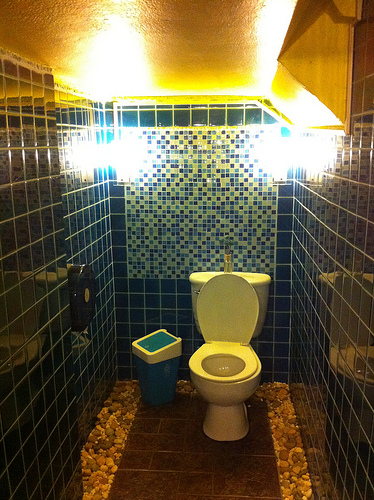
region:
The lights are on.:
[93, 123, 318, 195]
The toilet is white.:
[184, 266, 273, 447]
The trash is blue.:
[125, 326, 187, 414]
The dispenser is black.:
[58, 261, 99, 340]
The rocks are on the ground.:
[59, 376, 114, 497]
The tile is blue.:
[20, 202, 370, 413]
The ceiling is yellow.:
[4, 4, 338, 116]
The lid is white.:
[128, 327, 185, 362]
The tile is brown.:
[131, 402, 269, 498]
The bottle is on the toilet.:
[217, 234, 235, 271]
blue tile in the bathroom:
[148, 135, 290, 215]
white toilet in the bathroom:
[186, 261, 277, 430]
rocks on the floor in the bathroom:
[101, 365, 320, 497]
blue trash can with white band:
[130, 326, 206, 412]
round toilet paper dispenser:
[68, 258, 106, 358]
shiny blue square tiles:
[4, 99, 80, 440]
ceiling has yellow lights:
[45, 13, 368, 164]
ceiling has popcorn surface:
[76, 5, 234, 97]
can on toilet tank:
[213, 234, 245, 276]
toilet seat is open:
[198, 277, 256, 426]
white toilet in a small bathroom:
[188, 267, 275, 444]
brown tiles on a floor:
[107, 387, 284, 499]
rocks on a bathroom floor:
[75, 371, 316, 499]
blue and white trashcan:
[130, 321, 182, 405]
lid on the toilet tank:
[182, 265, 272, 287]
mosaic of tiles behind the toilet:
[117, 122, 277, 281]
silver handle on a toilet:
[192, 287, 212, 298]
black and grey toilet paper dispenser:
[60, 256, 100, 348]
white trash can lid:
[126, 326, 182, 367]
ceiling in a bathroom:
[0, 1, 360, 135]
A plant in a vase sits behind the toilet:
[214, 232, 238, 272]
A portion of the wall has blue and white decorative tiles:
[127, 134, 273, 236]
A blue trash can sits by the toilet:
[124, 311, 183, 414]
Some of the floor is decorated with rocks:
[266, 387, 306, 497]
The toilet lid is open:
[190, 270, 252, 383]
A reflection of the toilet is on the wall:
[0, 269, 47, 376]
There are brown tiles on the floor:
[142, 439, 183, 498]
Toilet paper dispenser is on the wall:
[63, 259, 95, 348]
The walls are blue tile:
[307, 366, 366, 478]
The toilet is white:
[184, 259, 276, 449]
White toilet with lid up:
[186, 268, 270, 442]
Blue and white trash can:
[129, 325, 183, 418]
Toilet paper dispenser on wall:
[65, 258, 99, 344]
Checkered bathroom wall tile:
[139, 200, 249, 231]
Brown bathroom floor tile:
[156, 440, 207, 483]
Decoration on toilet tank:
[216, 232, 237, 275]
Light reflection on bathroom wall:
[235, 125, 348, 186]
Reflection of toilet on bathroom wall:
[313, 268, 372, 396]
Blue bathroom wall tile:
[27, 374, 66, 469]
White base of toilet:
[198, 400, 252, 442]